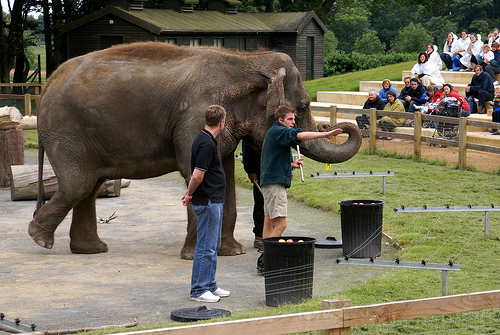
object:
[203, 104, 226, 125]
hair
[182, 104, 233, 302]
man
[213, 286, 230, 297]
sneaker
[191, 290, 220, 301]
sneaker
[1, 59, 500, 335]
ground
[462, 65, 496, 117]
crowd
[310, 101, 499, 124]
benches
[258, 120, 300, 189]
sweater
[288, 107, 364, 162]
trunk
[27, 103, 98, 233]
leg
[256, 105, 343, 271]
man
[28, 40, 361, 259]
elephant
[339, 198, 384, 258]
barrel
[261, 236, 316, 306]
barrel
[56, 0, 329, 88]
cabin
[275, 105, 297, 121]
hair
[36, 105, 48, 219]
tail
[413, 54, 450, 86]
people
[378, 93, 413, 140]
sitting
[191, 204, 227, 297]
jeans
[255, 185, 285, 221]
shorts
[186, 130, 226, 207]
polo shirt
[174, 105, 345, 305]
two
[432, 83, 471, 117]
person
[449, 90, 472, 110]
shirt